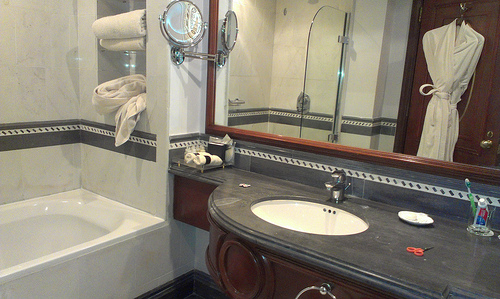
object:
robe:
[415, 17, 485, 162]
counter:
[206, 167, 500, 299]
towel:
[98, 37, 147, 52]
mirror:
[161, 0, 207, 50]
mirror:
[213, 0, 500, 185]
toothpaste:
[473, 198, 490, 229]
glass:
[462, 200, 499, 238]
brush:
[461, 176, 476, 215]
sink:
[253, 197, 370, 240]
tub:
[1, 187, 179, 298]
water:
[0, 206, 111, 272]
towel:
[91, 74, 148, 147]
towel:
[90, 8, 149, 40]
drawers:
[252, 247, 384, 298]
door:
[397, 0, 500, 171]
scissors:
[405, 244, 433, 257]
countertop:
[167, 158, 499, 296]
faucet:
[322, 168, 352, 205]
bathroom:
[0, 0, 500, 298]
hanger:
[393, 17, 486, 165]